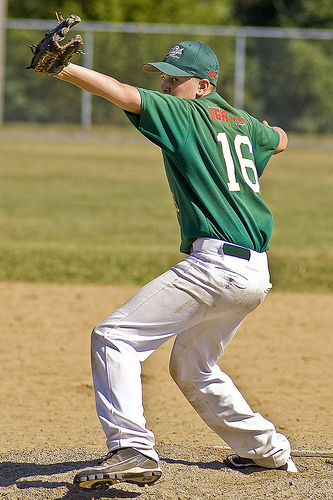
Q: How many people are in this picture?
A: One.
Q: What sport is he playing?
A: Baseball.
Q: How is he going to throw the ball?
A: With his right hand.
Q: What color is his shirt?
A: Green.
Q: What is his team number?
A: 16.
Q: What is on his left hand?
A: Baseball mitt.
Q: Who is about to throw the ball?
A: Player 16.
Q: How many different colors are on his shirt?
A: Three.